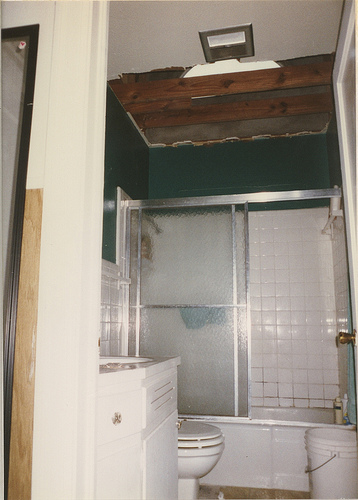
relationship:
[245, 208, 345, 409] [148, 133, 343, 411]
tiles on wall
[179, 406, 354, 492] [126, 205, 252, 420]
bathtub has doors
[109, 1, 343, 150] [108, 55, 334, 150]
ceiling has hole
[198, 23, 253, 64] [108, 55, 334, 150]
vent next to hole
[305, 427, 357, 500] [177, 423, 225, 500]
bucket in front of toilet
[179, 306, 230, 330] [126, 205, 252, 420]
towel on door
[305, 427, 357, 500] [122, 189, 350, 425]
bucket next to shower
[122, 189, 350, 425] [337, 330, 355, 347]
shower has doorknob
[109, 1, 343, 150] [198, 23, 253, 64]
ceiling has vent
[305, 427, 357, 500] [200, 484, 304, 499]
bucket on floor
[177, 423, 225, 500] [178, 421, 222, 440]
toilet has lid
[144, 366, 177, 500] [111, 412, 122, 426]
cabinets has knobs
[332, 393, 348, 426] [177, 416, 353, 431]
shampoo on ledge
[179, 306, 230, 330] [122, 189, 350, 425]
towel in shower